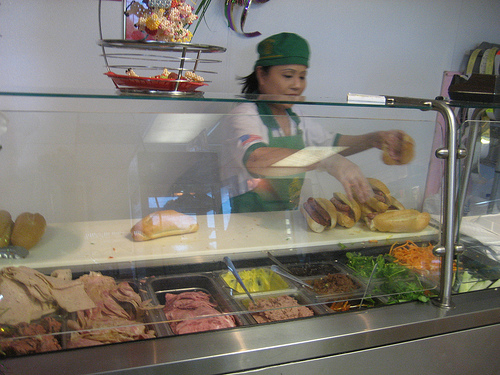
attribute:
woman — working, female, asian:
[210, 24, 420, 210]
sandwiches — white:
[296, 176, 432, 237]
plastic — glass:
[3, 108, 445, 332]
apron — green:
[231, 101, 312, 212]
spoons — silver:
[220, 251, 316, 307]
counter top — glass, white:
[9, 196, 435, 272]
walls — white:
[3, 3, 445, 183]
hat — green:
[252, 28, 316, 69]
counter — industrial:
[1, 211, 300, 274]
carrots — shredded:
[390, 237, 440, 268]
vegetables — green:
[348, 251, 425, 308]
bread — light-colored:
[124, 202, 201, 242]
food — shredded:
[389, 231, 451, 275]